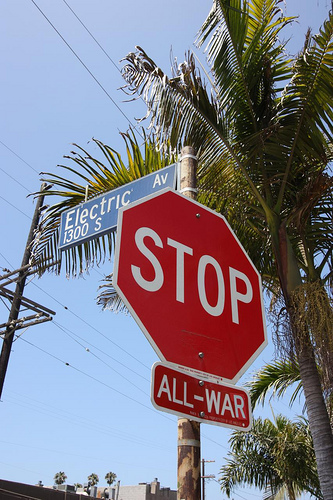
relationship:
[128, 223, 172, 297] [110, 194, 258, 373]
s on sign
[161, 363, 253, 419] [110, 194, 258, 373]
sign under sign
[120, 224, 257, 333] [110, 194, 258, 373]
stop on sign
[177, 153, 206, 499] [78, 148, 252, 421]
pole has signs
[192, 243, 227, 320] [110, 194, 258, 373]
o on sign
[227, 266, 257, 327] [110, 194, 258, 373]
p on sign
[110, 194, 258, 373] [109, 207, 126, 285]
sign with border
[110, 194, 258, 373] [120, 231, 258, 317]
sign with lettering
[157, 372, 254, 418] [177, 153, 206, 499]
all war on sign post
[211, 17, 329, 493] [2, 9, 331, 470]
trees in background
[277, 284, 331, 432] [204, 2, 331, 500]
trunk of tree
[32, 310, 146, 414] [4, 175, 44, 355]
cables on post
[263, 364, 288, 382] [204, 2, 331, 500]
leaf of tree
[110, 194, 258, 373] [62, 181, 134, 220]
sign with name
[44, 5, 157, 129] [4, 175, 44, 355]
wires attached to post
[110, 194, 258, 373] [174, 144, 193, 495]
sign on post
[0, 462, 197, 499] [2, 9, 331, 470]
buildings in background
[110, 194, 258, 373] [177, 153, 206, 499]
sign attached to pole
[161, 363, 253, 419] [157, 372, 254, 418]
sign says all war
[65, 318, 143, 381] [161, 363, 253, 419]
power lines behind sign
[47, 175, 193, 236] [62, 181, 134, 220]
sign says name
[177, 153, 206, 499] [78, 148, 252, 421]
pole for signs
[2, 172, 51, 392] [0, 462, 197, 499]
pole next to buildings